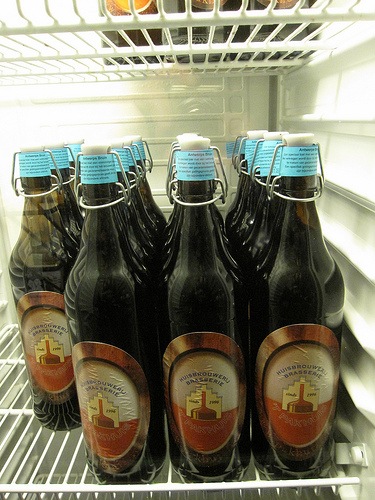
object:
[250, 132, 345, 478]
bottle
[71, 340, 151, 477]
label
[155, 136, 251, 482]
bottle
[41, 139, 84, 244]
bottle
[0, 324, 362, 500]
shelf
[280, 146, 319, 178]
lable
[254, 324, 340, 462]
label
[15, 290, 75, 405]
label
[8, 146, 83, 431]
bottle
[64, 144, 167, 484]
bottle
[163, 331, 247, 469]
label